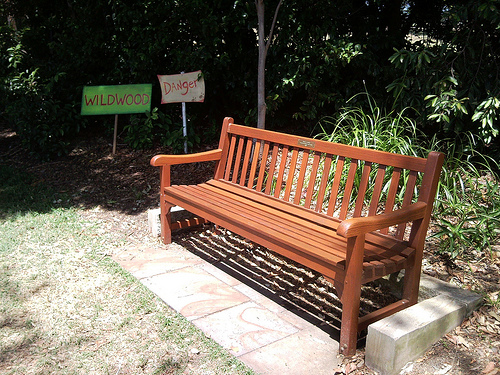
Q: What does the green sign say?
A: Wildwood.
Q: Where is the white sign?
A: Next to the green sign.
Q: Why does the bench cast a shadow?
A: It is sunny.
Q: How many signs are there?
A: Two.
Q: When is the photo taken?
A: Daytime.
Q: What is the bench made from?
A: Wood.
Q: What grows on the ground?
A: Grass.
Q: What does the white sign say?
A: Danger.